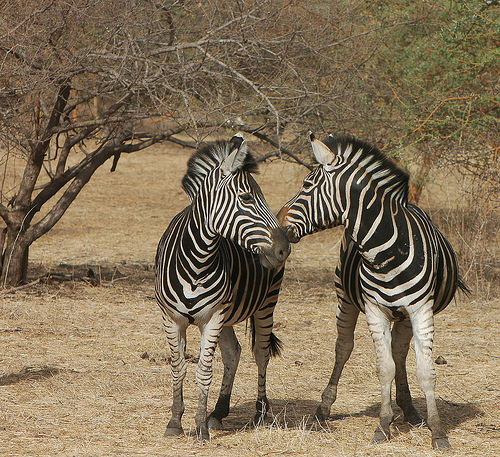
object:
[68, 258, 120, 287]
objects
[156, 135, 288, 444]
zebra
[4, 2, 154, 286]
tree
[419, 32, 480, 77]
leaves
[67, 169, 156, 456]
ground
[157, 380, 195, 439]
dirt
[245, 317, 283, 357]
tail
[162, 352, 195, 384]
knuckle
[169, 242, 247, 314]
stripe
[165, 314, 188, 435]
leg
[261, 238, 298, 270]
nose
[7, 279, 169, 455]
grass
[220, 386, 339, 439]
shadows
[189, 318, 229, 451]
legs